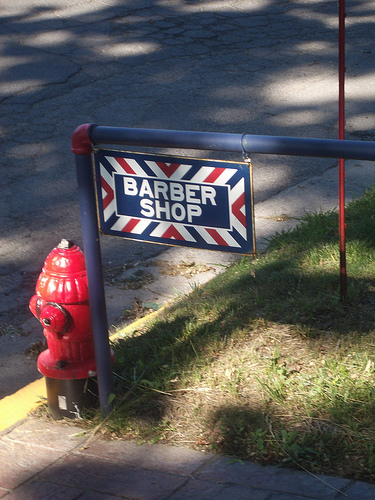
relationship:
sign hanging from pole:
[89, 145, 257, 256] [66, 123, 374, 160]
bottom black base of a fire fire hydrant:
[46, 376, 99, 420] [28, 238, 96, 423]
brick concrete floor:
[32, 452, 124, 459] [0, 416, 375, 499]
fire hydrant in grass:
[28, 238, 96, 423] [115, 336, 329, 433]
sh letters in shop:
[142, 193, 166, 246] [108, 169, 232, 263]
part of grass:
[150, 355, 237, 435] [87, 176, 374, 481]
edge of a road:
[13, 415, 47, 447] [0, 0, 372, 401]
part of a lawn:
[117, 335, 170, 402] [87, 176, 374, 481]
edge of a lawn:
[101, 413, 216, 453] [87, 176, 374, 481]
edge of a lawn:
[34, 411, 375, 487] [87, 176, 374, 481]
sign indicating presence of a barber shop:
[89, 145, 257, 256] [101, 160, 351, 276]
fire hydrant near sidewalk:
[28, 238, 96, 423] [30, 460, 165, 500]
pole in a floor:
[337, 1, 349, 308] [0, 416, 375, 499]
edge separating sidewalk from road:
[0, 414, 31, 441] [0, 0, 372, 401]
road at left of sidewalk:
[4, 0, 100, 410] [26, 439, 133, 475]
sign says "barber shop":
[89, 145, 257, 256] [96, 183, 241, 215]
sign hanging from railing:
[89, 145, 257, 256] [70, 123, 373, 416]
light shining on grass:
[158, 315, 373, 450] [87, 176, 374, 481]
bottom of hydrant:
[42, 375, 99, 422] [28, 238, 96, 423]